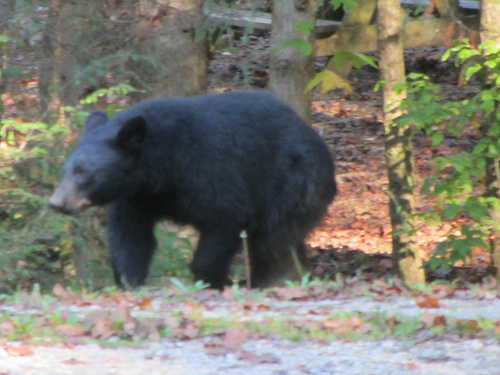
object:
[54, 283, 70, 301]
leaf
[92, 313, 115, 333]
leaf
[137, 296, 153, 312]
leaf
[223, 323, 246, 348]
leaf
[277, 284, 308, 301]
leaf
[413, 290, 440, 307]
leaf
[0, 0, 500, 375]
ground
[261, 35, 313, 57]
leaf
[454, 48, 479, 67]
leaf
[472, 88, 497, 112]
leaf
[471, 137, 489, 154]
leaf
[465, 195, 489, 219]
leaf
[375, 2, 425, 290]
tree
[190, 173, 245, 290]
leg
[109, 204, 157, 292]
leg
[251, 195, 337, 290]
leg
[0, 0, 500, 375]
woods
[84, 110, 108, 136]
ear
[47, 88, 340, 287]
fur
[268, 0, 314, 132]
tree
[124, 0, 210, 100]
tree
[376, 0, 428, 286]
trunk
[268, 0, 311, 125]
trunk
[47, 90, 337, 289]
bear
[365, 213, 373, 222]
leaf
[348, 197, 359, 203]
leaf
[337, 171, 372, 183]
leaf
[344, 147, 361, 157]
leaf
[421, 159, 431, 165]
leaf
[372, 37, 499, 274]
brown leaves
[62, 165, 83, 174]
eyes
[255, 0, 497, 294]
leaves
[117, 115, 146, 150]
ear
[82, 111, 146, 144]
ears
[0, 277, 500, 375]
road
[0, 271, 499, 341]
dead leaves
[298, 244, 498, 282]
shadow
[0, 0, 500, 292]
forest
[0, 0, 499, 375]
floor